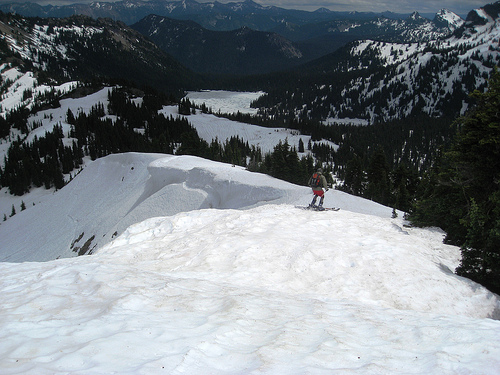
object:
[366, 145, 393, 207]
tree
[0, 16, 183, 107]
mountain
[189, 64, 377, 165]
field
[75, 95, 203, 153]
lights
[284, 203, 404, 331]
ocean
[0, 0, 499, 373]
banners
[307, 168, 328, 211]
person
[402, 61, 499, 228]
trees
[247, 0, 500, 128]
large mountain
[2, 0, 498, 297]
forrest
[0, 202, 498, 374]
snowy field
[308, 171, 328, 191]
jacket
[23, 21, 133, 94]
snow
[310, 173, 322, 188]
backpack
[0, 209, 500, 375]
hill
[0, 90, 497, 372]
snow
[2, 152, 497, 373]
ground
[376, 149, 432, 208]
thick foliage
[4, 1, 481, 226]
mountain range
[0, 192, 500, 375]
field